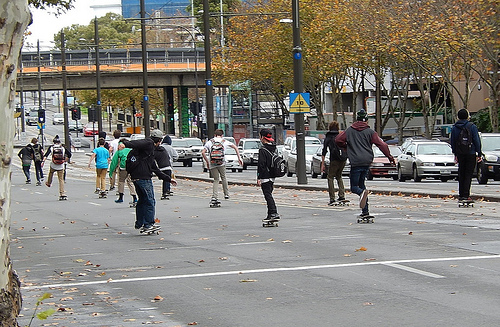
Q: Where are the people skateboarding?
A: Street.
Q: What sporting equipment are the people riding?
A: Skateboards.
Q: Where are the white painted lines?
A: Road.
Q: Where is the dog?
A: There is no dog.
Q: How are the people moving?
A: Skateboards.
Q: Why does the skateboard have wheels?
A: To move.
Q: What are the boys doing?
A: Skateboarding.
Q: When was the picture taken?
A: Afternoon.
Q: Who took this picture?
A: A news reporter.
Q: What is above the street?
A: A bridge.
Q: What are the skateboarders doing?
A: Skating.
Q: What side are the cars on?
A: Right.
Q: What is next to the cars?
A: Trees.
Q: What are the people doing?
A: Riding skateboards.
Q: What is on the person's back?
A: A black and white backpack.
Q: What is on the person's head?
A: A black and red hat.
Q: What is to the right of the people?
A: A line of cars.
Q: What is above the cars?
A: A line of trees with yellow leaves.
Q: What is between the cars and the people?
A: Street poles.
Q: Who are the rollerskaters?
A: Young men and boys.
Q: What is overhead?
A: A bridge.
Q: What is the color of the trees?
A: Yellowish brown.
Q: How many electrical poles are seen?
A: Seven.